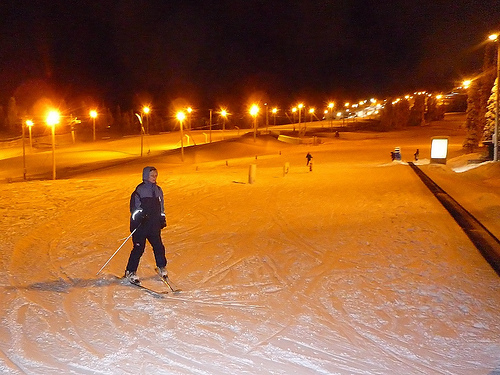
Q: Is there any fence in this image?
A: No, there are no fences.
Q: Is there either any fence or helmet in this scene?
A: No, there are no fences or helmets.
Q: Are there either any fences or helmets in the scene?
A: No, there are no fences or helmets.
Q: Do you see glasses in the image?
A: No, there are no glasses.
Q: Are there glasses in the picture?
A: No, there are no glasses.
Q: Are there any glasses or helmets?
A: No, there are no glasses or helmets.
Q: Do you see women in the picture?
A: Yes, there is a woman.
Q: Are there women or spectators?
A: Yes, there is a woman.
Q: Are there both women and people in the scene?
A: Yes, there are both a woman and people.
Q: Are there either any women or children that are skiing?
A: Yes, the woman is skiing.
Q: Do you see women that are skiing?
A: Yes, there is a woman that is skiing.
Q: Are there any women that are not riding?
A: Yes, there is a woman that is skiing.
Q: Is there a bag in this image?
A: No, there are no bags.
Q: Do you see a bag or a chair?
A: No, there are no bags or chairs.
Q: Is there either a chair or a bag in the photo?
A: No, there are no bags or chairs.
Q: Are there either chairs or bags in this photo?
A: No, there are no bags or chairs.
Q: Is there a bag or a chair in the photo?
A: No, there are no bags or chairs.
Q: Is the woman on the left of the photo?
A: Yes, the woman is on the left of the image.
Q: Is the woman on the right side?
A: No, the woman is on the left of the image.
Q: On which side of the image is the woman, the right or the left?
A: The woman is on the left of the image.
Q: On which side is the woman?
A: The woman is on the left of the image.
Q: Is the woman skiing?
A: Yes, the woman is skiing.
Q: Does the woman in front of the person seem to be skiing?
A: Yes, the woman is skiing.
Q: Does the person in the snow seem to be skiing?
A: Yes, the woman is skiing.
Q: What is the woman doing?
A: The woman is skiing.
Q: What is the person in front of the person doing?
A: The woman is skiing.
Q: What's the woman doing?
A: The woman is skiing.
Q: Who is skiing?
A: The woman is skiing.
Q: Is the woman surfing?
A: No, the woman is skiing.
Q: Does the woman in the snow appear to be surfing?
A: No, the woman is skiing.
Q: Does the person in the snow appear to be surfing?
A: No, the woman is skiing.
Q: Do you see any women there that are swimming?
A: No, there is a woman but she is skiing.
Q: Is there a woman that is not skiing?
A: No, there is a woman but she is skiing.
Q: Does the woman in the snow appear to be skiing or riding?
A: The woman is skiing.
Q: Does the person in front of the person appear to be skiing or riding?
A: The woman is skiing.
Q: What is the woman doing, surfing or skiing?
A: The woman is skiing.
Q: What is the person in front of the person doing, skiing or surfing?
A: The woman is skiing.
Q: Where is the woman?
A: The woman is in the snow.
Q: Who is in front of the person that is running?
A: The woman is in front of the person.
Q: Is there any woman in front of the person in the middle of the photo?
A: Yes, there is a woman in front of the person.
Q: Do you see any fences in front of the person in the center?
A: No, there is a woman in front of the person.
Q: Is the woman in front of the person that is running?
A: Yes, the woman is in front of the person.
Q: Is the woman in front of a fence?
A: No, the woman is in front of the person.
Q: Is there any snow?
A: Yes, there is snow.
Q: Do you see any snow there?
A: Yes, there is snow.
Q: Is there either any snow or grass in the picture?
A: Yes, there is snow.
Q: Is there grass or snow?
A: Yes, there is snow.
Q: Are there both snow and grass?
A: No, there is snow but no grass.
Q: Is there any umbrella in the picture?
A: No, there are no umbrellas.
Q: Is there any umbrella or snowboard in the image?
A: No, there are no umbrellas or snowboards.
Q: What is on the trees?
A: The snow is on the trees.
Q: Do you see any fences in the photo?
A: No, there are no fences.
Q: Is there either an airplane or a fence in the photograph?
A: No, there are no fences or airplanes.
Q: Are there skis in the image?
A: Yes, there are skis.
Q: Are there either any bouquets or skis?
A: Yes, there are skis.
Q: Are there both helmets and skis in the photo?
A: No, there are skis but no helmets.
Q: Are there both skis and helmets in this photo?
A: No, there are skis but no helmets.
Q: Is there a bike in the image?
A: No, there are no bikes.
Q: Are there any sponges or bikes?
A: No, there are no bikes or sponges.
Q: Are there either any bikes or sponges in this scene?
A: No, there are no bikes or sponges.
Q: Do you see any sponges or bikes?
A: No, there are no bikes or sponges.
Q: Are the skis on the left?
A: Yes, the skis are on the left of the image.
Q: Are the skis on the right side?
A: No, the skis are on the left of the image.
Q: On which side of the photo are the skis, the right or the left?
A: The skis are on the left of the image.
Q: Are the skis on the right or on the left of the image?
A: The skis are on the left of the image.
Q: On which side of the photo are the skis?
A: The skis are on the left of the image.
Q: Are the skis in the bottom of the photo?
A: Yes, the skis are in the bottom of the image.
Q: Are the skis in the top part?
A: No, the skis are in the bottom of the image.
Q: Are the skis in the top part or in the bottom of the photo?
A: The skis are in the bottom of the image.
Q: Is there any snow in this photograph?
A: Yes, there is snow.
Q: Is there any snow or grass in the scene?
A: Yes, there is snow.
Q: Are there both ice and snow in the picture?
A: No, there is snow but no ice.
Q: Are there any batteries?
A: No, there are no batteries.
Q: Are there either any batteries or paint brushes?
A: No, there are no batteries or paint brushes.